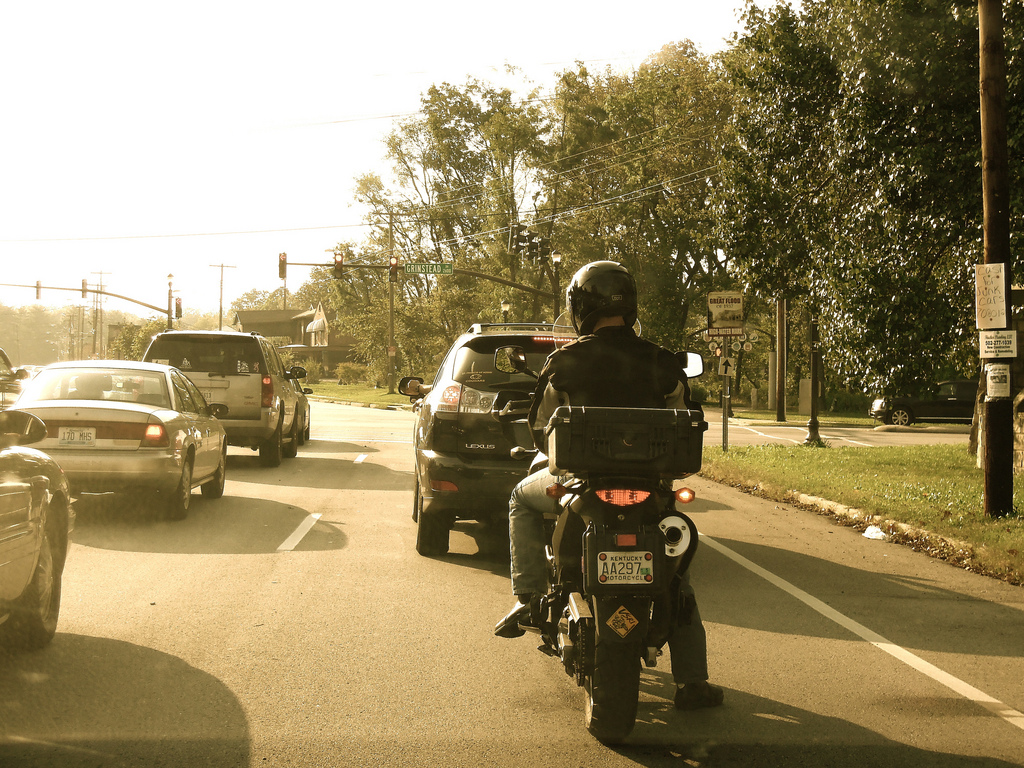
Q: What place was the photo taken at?
A: It was taken at the road.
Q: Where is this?
A: This is at the road.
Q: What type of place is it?
A: It is a road.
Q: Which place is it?
A: It is a road.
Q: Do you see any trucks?
A: No, there are no trucks.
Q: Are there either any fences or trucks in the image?
A: No, there are no trucks or fences.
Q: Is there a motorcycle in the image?
A: Yes, there is a motorcycle.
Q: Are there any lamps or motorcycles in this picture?
A: Yes, there is a motorcycle.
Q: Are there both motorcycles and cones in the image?
A: No, there is a motorcycle but no cones.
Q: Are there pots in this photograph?
A: No, there are no pots.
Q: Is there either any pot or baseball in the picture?
A: No, there are no pots or baseballs.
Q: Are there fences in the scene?
A: No, there are no fences.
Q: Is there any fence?
A: No, there are no fences.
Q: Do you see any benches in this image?
A: No, there are no benches.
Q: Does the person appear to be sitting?
A: Yes, the person is sitting.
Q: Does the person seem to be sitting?
A: Yes, the person is sitting.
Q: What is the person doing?
A: The person is sitting.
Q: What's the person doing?
A: The person is sitting.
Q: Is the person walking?
A: No, the person is sitting.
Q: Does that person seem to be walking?
A: No, the person is sitting.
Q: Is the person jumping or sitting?
A: The person is sitting.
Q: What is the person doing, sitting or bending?
A: The person is sitting.